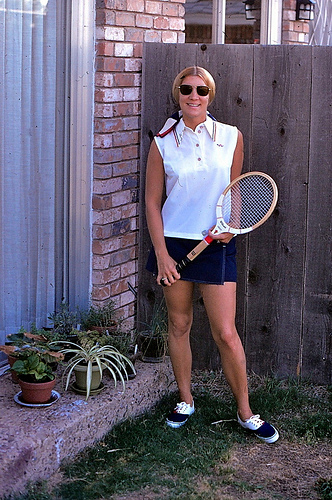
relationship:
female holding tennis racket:
[147, 65, 283, 447] [160, 170, 278, 287]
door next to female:
[0, 0, 92, 356] [147, 65, 283, 447]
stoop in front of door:
[0, 346, 178, 498] [1, 0, 95, 320]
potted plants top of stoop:
[3, 312, 166, 409] [0, 346, 178, 498]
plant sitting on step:
[14, 352, 64, 379] [0, 354, 178, 497]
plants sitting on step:
[48, 340, 137, 401] [1, 339, 182, 499]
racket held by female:
[152, 170, 280, 282] [147, 65, 283, 447]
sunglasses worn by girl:
[176, 83, 212, 98] [144, 65, 242, 335]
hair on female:
[164, 63, 219, 102] [147, 65, 283, 447]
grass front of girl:
[82, 419, 234, 483] [139, 72, 244, 212]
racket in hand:
[159, 170, 281, 287] [207, 220, 234, 248]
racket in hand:
[159, 170, 281, 287] [150, 250, 181, 287]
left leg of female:
[197, 279, 257, 421] [147, 65, 283, 447]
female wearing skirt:
[147, 65, 283, 447] [149, 237, 240, 283]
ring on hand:
[216, 239, 219, 243] [207, 221, 234, 243]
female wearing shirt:
[147, 65, 283, 447] [153, 116, 238, 242]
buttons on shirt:
[191, 123, 205, 165] [153, 116, 238, 242]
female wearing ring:
[147, 65, 283, 447] [159, 275, 169, 282]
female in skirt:
[147, 65, 283, 447] [143, 226, 242, 284]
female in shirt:
[147, 65, 283, 447] [154, 110, 237, 240]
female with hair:
[147, 65, 283, 447] [167, 64, 215, 111]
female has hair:
[147, 65, 283, 447] [147, 62, 216, 97]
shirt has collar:
[162, 119, 231, 235] [171, 115, 218, 146]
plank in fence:
[131, 40, 198, 361] [229, 29, 325, 158]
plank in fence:
[195, 41, 252, 370] [229, 29, 325, 158]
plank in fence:
[244, 40, 312, 393] [229, 29, 325, 158]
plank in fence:
[299, 44, 331, 385] [229, 29, 325, 158]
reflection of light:
[242, 0, 260, 19] [293, 0, 315, 23]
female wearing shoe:
[147, 65, 283, 447] [234, 409, 278, 444]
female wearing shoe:
[147, 65, 283, 447] [164, 399, 195, 428]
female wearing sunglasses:
[147, 65, 283, 447] [174, 83, 211, 96]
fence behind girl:
[142, 38, 330, 324] [139, 60, 258, 323]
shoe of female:
[167, 399, 195, 430] [147, 65, 283, 447]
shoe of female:
[236, 409, 279, 443] [147, 65, 283, 447]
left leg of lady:
[201, 281, 252, 420] [138, 58, 288, 454]